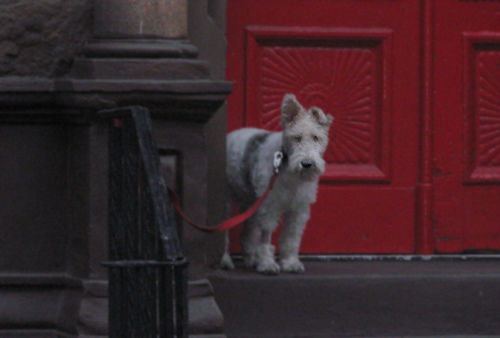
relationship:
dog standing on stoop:
[220, 94, 333, 276] [204, 256, 499, 337]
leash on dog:
[111, 116, 284, 235] [220, 94, 333, 276]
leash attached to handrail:
[111, 116, 284, 235] [96, 106, 188, 338]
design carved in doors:
[263, 46, 373, 165] [227, 1, 499, 256]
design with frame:
[263, 46, 373, 165] [242, 25, 394, 183]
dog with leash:
[220, 94, 333, 276] [111, 116, 284, 235]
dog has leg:
[220, 94, 333, 276] [256, 206, 282, 276]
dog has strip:
[220, 94, 333, 276] [241, 128, 270, 201]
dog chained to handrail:
[220, 94, 333, 276] [96, 106, 188, 338]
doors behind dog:
[227, 1, 499, 256] [220, 94, 333, 276]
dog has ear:
[220, 94, 333, 276] [309, 107, 334, 127]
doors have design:
[227, 1, 499, 256] [263, 46, 373, 165]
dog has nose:
[220, 94, 333, 276] [300, 161, 313, 169]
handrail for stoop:
[96, 106, 188, 338] [204, 256, 499, 337]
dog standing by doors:
[220, 94, 333, 276] [227, 1, 499, 256]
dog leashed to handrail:
[220, 94, 333, 276] [96, 106, 188, 338]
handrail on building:
[96, 106, 188, 338] [1, 0, 498, 338]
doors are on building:
[227, 1, 499, 256] [1, 0, 498, 338]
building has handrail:
[1, 0, 498, 338] [96, 106, 188, 338]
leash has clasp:
[111, 116, 284, 235] [274, 151, 283, 173]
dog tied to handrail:
[220, 94, 333, 276] [96, 106, 188, 338]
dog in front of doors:
[220, 94, 333, 276] [227, 1, 499, 256]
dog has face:
[220, 94, 333, 276] [289, 125, 323, 175]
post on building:
[54, 1, 233, 338] [1, 0, 498, 338]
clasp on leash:
[274, 151, 283, 173] [111, 116, 284, 235]